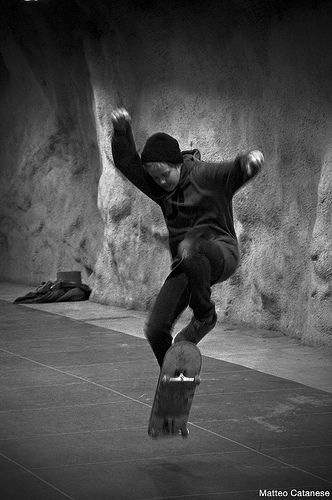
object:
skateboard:
[144, 337, 210, 440]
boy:
[100, 91, 266, 368]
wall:
[8, 33, 331, 316]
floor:
[0, 297, 332, 499]